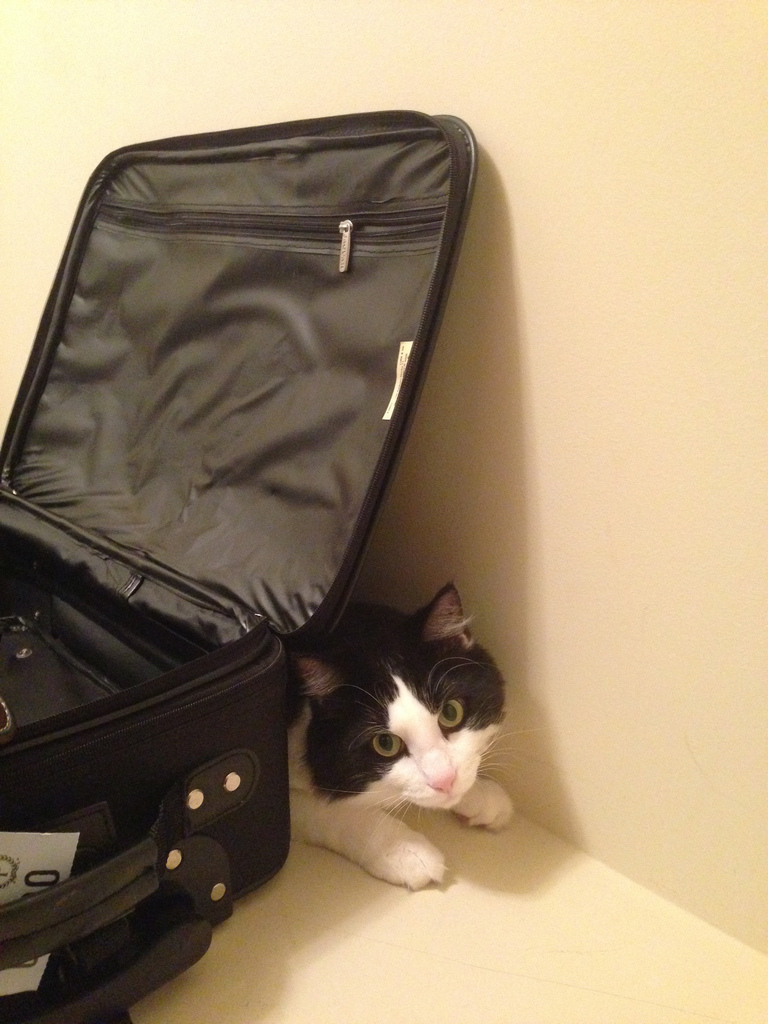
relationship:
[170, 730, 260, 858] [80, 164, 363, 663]
rivets in leather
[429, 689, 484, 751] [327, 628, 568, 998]
eye of animal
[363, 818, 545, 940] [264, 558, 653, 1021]
paw of animal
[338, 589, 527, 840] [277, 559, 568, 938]
face of cat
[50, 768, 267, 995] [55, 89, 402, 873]
handles on suitcase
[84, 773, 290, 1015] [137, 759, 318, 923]
handle with trim